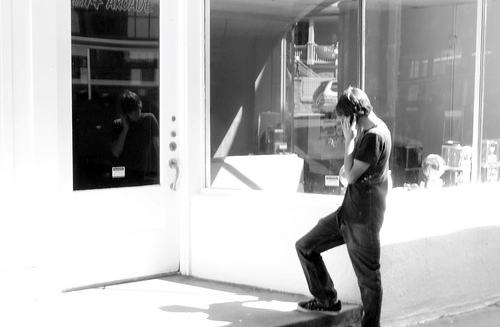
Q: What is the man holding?
A: The phone.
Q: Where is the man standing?
A: On the steps.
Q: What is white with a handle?
A: The door.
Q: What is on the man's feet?
A: Sneakers.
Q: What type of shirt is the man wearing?
A: Short sleeved.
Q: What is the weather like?
A: Sunny.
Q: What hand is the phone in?
A: Left hand.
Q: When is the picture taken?
A: Daytime.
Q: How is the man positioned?
A: Standing.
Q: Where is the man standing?
A: On a sidewalk.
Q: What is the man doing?
A: Talking on phone.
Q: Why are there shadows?
A: Sun is setting.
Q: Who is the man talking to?
A: Not sure.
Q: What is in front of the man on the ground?
A: Shadow.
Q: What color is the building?
A: White.